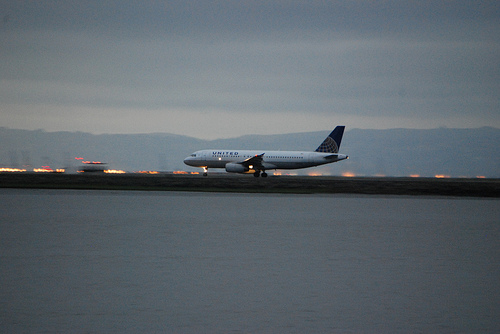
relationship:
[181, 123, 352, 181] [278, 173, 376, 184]
plane parked on tarmac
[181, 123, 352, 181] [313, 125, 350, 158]
plane has a tail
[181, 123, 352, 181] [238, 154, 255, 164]
plane has small lights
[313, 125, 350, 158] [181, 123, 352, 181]
tail on plane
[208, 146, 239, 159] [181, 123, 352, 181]
logo written on side of plane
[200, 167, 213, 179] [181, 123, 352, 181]
front wheel down on plane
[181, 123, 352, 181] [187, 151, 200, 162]
plane has front windows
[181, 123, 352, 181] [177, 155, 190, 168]
plane has a front nose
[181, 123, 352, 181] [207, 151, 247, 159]
plane has side windows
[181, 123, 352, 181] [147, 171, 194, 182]
airplane getting ready to land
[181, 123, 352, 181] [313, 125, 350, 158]
plane has a dark tail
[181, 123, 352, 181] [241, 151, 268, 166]
plane has a dark wing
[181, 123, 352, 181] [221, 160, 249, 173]
plane has a jet engine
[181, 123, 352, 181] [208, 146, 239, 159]
plane has black letters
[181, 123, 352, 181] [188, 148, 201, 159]
plane has cockpit windows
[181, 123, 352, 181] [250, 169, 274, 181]
plane has rear wheels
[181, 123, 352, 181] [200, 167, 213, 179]
plane has a front wheel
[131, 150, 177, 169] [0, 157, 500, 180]
background has airport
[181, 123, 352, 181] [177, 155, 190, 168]
united airlines commercial plane has nose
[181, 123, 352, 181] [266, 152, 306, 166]
united airlines commercial plane has windows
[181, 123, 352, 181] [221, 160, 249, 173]
united airlines commercial plane has turbines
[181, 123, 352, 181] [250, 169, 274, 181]
united airlines commercial plane has wheels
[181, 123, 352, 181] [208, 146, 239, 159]
united airlines commercial plane has written logo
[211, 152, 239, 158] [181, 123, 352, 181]
logo on united airlines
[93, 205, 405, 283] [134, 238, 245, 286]
small lake has many ripples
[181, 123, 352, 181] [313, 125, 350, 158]
airplane has a blue tail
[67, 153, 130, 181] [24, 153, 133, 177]
airport has bright lights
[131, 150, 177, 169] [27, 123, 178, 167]
background has a mountain range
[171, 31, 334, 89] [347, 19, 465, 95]
sky has clouds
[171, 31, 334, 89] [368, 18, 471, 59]
sky has hazy clouds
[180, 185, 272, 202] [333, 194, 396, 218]
shore has clear water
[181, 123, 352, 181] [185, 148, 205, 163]
plane has a cockpit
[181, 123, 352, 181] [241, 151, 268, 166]
plane has a wing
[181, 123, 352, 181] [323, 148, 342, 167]
plane has a back wing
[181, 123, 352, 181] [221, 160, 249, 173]
plane has a turbine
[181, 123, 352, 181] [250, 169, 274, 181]
plane has wheels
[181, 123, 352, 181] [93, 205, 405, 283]
plane next to body of water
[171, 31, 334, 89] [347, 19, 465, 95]
sky has many clouds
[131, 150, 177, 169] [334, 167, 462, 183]
background has lights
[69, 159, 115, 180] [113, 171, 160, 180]
building on field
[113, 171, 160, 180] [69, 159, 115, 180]
field has a building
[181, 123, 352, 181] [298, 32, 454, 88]
plane flying in mid air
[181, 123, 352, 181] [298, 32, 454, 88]
plane in mid air